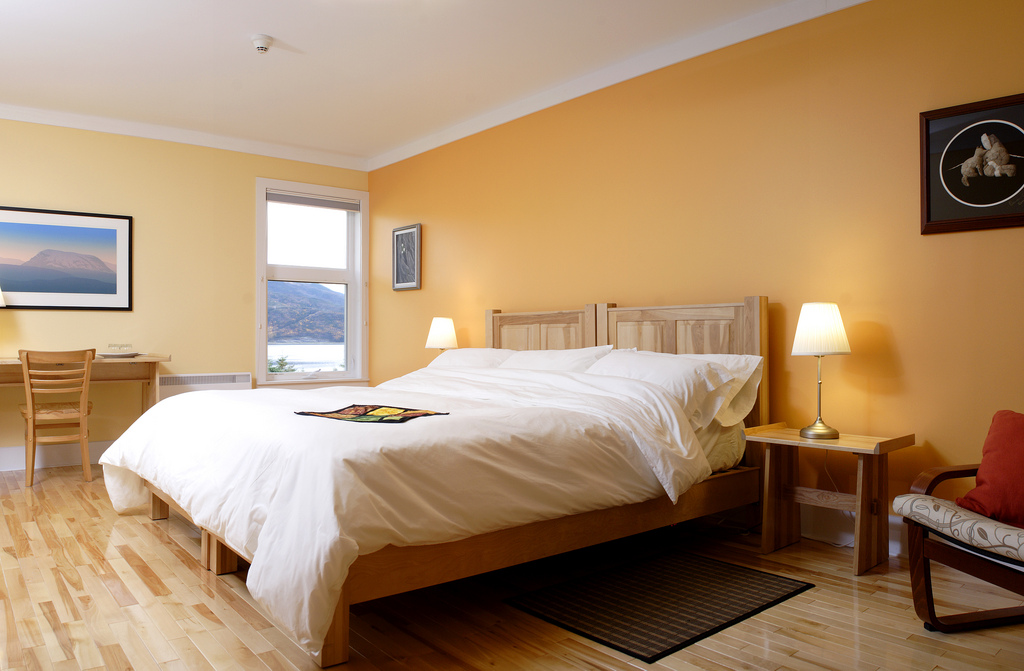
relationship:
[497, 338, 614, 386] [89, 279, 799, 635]
pillow on bed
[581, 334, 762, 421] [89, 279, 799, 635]
pillow on bed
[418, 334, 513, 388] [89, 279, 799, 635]
pillow on bed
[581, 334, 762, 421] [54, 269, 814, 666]
pillow on bed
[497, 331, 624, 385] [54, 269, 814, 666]
pillow on bed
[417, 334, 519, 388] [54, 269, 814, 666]
pillow on bed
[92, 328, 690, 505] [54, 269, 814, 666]
blanket on bed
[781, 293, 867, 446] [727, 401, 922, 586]
lamp on stand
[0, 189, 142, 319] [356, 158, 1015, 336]
picture on wall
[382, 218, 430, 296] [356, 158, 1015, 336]
picture on wall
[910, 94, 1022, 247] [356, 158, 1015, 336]
picture on wall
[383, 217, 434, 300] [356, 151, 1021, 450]
picture on wall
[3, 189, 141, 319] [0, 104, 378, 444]
picture on wall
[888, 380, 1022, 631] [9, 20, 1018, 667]
chair in room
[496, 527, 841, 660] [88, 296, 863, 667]
rug under bed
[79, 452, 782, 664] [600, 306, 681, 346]
frame has panel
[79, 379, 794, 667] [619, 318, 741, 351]
frame has panel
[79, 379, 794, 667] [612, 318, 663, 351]
frame has panel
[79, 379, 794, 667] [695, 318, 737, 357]
frame has panel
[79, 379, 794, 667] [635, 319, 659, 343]
frame has panel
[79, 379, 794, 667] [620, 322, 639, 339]
frame has panel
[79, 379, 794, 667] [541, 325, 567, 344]
frame has panel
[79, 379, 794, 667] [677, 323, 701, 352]
frame has panel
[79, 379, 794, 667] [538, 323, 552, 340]
frame has panel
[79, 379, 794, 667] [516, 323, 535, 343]
frame has panel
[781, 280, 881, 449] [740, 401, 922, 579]
lamp on stand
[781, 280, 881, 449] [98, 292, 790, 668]
lamp next to bed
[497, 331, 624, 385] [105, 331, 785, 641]
pillow on bed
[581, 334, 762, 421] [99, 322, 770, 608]
pillow on bed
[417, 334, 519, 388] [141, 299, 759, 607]
pillow on bed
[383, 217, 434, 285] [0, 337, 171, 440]
picture above desk